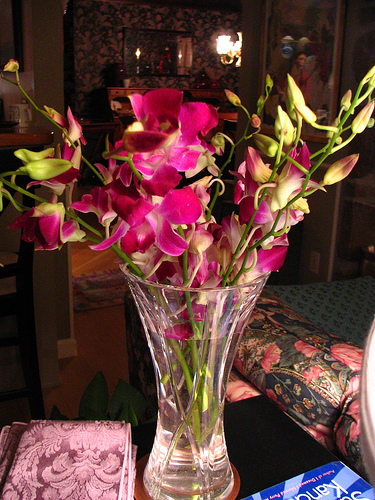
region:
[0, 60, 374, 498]
Flowers in a vase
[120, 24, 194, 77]
Mirror on the wall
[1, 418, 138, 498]
Books on the table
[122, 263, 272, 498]
Glass vase on the table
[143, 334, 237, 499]
Water in the vase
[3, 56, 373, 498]
Vase filled with pink flowers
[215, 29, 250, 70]
The light is on.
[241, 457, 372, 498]
A book is on the table.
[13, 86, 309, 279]
The flowers are pink.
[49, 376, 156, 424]
A plant is by the wall.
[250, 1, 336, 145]
A painting is on the wall.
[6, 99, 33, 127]
A coffee mug is on the shelf.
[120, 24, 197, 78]
A mirror is on the wall.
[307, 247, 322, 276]
An outlet is on the wall.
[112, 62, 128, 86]
A vase is on the shelf.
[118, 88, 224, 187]
a pink flower in a vase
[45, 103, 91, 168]
a pink flower in a vase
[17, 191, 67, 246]
a pink flower in a vase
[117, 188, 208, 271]
a pink flower in a vase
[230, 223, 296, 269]
a pink flower in a vase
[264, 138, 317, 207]
a pink flower in a vase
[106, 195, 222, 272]
a pink flower bloomed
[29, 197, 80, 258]
a pink flower bloomed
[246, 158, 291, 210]
a pink flower bloomed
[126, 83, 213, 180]
a pink flower bloomed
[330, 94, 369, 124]
flower in a vase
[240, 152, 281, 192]
flower in a vase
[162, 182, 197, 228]
flower in a vase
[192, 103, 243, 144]
flower in a vase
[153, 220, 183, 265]
flower in a vase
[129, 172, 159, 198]
flower in a vase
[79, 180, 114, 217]
flower in a vase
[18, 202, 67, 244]
flower in a vase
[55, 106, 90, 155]
flower in a vase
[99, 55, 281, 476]
flowers in a vase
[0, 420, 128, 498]
a pink folded up cloth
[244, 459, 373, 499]
part of a book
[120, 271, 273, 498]
a clear, glass vase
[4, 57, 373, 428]
pink flowers placed inside of a vase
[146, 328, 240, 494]
water inside of vase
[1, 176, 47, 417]
part of a wooden chair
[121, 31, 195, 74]
a mirror on the wall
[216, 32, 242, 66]
light fixture on the wall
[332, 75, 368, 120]
flowers in a vase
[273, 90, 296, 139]
flower in a vase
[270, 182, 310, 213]
flower in a vase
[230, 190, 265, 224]
flower in a vase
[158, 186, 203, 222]
the bright pink flower petal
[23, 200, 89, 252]
A flower on a stem.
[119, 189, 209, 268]
A flower on a stem.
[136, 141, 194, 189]
A flower on a stem.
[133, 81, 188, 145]
A flower on a stem.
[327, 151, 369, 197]
A flower on a stem.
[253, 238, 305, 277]
A flower on a stem.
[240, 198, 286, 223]
A flower on a stem.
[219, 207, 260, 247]
A flower on a stem.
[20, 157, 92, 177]
A flower on a stem.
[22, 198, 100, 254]
A flower on a stem.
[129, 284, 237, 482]
a vase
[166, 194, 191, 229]
a flower petal